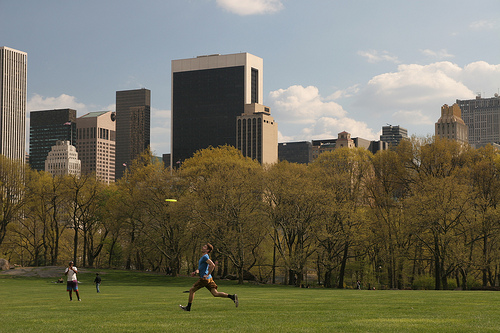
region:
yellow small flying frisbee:
[157, 197, 207, 210]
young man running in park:
[160, 228, 255, 318]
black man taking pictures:
[58, 255, 92, 297]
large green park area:
[22, 279, 487, 331]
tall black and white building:
[170, 52, 279, 217]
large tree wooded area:
[40, 173, 470, 283]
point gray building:
[40, 130, 97, 200]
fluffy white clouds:
[277, 60, 499, 156]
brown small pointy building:
[437, 104, 476, 183]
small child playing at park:
[94, 265, 124, 287]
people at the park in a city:
[5, 4, 490, 331]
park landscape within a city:
[5, 8, 280, 329]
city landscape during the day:
[1, 0, 496, 205]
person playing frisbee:
[6, 165, 316, 325]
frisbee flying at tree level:
[28, 140, 405, 240]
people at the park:
[5, 190, 306, 330]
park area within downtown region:
[12, 0, 492, 326]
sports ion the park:
[1, 163, 344, 324]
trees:
[232, 137, 497, 304]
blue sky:
[259, 5, 493, 129]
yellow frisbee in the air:
[160, 193, 179, 208]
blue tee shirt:
[192, 253, 217, 275]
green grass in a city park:
[5, 273, 496, 332]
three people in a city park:
[53, 236, 242, 315]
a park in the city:
[0, 136, 497, 329]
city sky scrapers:
[2, 40, 265, 181]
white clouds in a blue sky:
[272, 54, 498, 149]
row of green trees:
[2, 137, 499, 277]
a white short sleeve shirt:
[64, 265, 79, 285]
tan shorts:
[192, 275, 217, 292]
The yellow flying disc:
[162, 193, 180, 206]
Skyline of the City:
[2, 37, 497, 137]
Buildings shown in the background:
[1, 37, 498, 183]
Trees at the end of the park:
[1, 135, 495, 292]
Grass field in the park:
[1, 265, 497, 332]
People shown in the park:
[58, 241, 241, 311]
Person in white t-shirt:
[60, 258, 85, 304]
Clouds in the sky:
[29, 0, 498, 143]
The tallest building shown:
[0, 43, 30, 178]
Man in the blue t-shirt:
[170, 237, 245, 312]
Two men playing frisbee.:
[40, 228, 240, 325]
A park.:
[2, 150, 492, 327]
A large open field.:
[10, 250, 490, 327]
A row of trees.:
[0, 140, 492, 282]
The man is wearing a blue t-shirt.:
[177, 240, 237, 315]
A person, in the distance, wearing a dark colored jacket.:
[90, 267, 105, 292]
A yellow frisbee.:
[155, 190, 182, 210]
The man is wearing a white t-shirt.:
[61, 260, 77, 300]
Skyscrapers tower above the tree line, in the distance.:
[0, 35, 490, 165]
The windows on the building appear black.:
[170, 58, 242, 154]